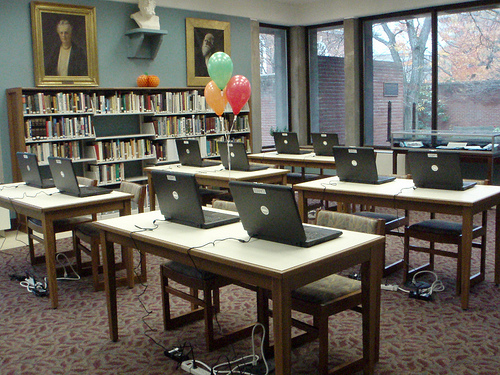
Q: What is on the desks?
A: Laptops.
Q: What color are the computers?
A: Black.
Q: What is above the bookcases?
A: Paintings.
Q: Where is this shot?
A: Class room.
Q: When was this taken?
A: Daytime.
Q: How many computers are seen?
A: 10.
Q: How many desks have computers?
A: 5.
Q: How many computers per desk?
A: 2.